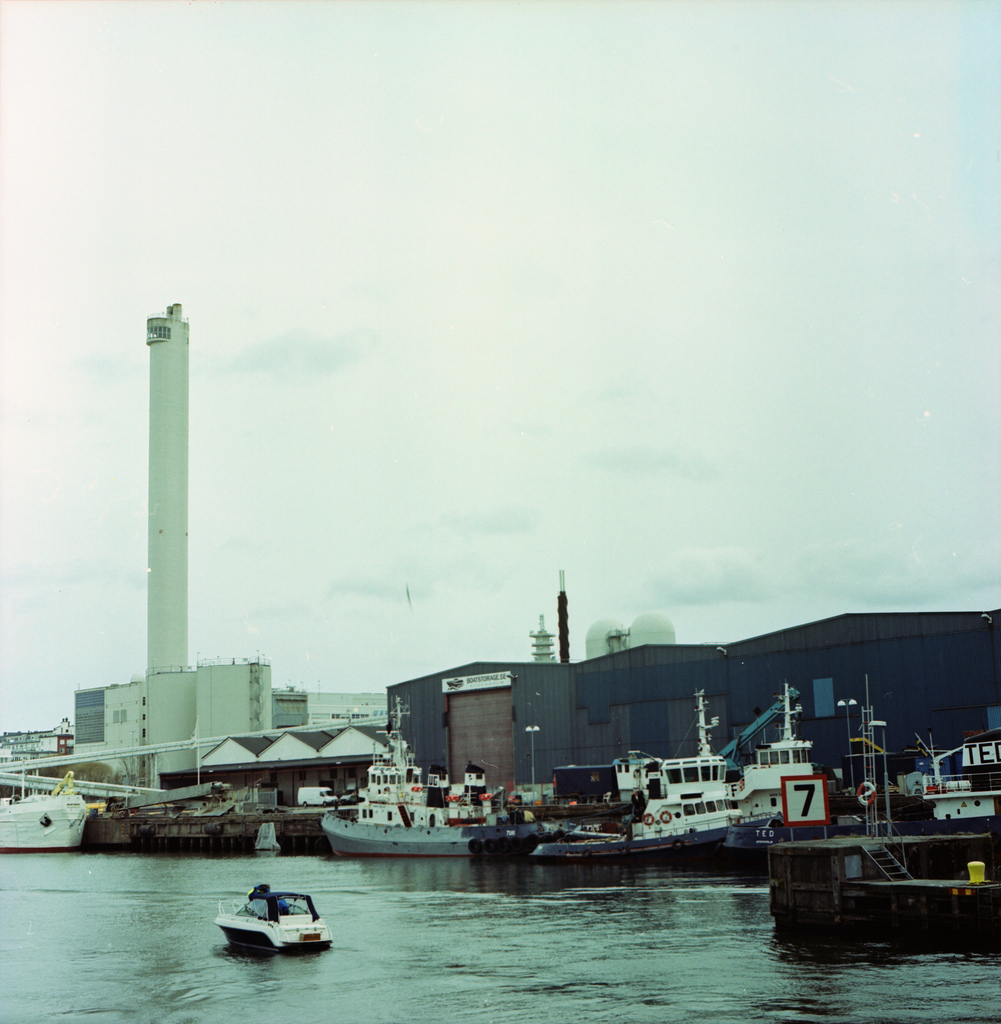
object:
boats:
[32, 671, 908, 881]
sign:
[772, 764, 855, 849]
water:
[38, 862, 682, 991]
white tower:
[122, 287, 213, 671]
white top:
[353, 736, 448, 827]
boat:
[288, 684, 584, 868]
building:
[353, 581, 969, 802]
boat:
[208, 863, 336, 971]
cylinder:
[145, 299, 214, 663]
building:
[356, 570, 958, 865]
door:
[479, 764, 611, 827]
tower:
[125, 291, 245, 749]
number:
[778, 777, 827, 846]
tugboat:
[206, 877, 345, 962]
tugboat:
[200, 851, 352, 980]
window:
[202, 871, 331, 972]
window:
[220, 889, 329, 957]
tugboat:
[209, 860, 338, 961]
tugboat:
[203, 873, 348, 968]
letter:
[460, 671, 505, 680]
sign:
[765, 774, 860, 826]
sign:
[781, 758, 860, 859]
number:
[788, 788, 820, 820]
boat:
[211, 857, 340, 955]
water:
[448, 925, 661, 1008]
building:
[382, 654, 806, 897]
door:
[564, 751, 619, 820]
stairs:
[18, 753, 238, 822]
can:
[966, 857, 969, 892]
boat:
[310, 767, 529, 890]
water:
[479, 941, 738, 990]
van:
[5, 764, 125, 863]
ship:
[300, 758, 821, 963]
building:
[357, 618, 941, 746]